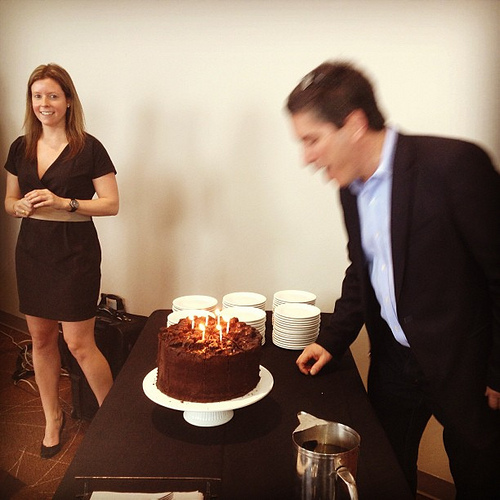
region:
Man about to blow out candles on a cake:
[280, 55, 498, 497]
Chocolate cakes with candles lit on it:
[154, 307, 263, 404]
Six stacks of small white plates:
[166, 289, 321, 353]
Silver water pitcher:
[288, 407, 361, 499]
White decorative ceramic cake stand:
[141, 363, 275, 428]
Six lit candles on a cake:
[185, 308, 234, 342]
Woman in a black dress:
[2, 60, 122, 460]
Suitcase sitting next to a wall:
[70, 288, 146, 420]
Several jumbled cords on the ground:
[8, 326, 74, 393]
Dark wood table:
[48, 310, 398, 498]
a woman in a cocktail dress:
[5, 62, 122, 459]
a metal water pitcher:
[285, 405, 369, 496]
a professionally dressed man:
[279, 69, 499, 490]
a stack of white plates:
[268, 298, 330, 358]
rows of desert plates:
[170, 283, 325, 355]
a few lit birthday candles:
[184, 306, 235, 345]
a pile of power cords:
[8, 328, 55, 395]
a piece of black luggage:
[54, 290, 149, 435]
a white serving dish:
[138, 357, 278, 429]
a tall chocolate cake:
[151, 313, 267, 400]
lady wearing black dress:
[0, 48, 125, 448]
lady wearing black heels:
[23, 397, 111, 477]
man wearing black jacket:
[272, 72, 499, 498]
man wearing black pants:
[362, 331, 499, 488]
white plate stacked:
[156, 283, 338, 387]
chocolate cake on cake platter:
[125, 285, 285, 447]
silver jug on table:
[272, 392, 397, 498]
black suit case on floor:
[60, 276, 180, 448]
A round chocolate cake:
[152, 312, 267, 404]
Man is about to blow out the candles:
[184, 63, 385, 360]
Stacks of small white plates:
[168, 285, 324, 354]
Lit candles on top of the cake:
[181, 307, 239, 347]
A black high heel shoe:
[36, 401, 72, 464]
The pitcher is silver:
[286, 401, 368, 499]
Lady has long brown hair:
[16, 60, 90, 168]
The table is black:
[51, 300, 415, 499]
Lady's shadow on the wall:
[113, 107, 191, 314]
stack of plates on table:
[280, 289, 312, 304]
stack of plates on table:
[246, 309, 268, 329]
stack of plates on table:
[225, 291, 265, 305]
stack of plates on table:
[170, 287, 215, 309]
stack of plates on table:
[166, 307, 195, 323]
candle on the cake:
[215, 327, 227, 339]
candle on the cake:
[223, 318, 230, 330]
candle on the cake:
[201, 320, 213, 343]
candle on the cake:
[184, 317, 195, 328]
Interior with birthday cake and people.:
[5, 4, 497, 494]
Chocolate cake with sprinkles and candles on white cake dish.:
[143, 320, 265, 431]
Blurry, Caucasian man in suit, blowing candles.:
[270, 67, 484, 482]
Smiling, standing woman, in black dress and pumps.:
[0, 53, 115, 455]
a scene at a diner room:
[14, 31, 494, 416]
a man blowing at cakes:
[130, 51, 494, 498]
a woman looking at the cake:
[0, 50, 162, 461]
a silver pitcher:
[280, 398, 370, 498]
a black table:
[44, 301, 431, 498]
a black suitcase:
[57, 282, 169, 439]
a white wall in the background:
[69, 15, 493, 307]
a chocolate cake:
[133, 302, 285, 445]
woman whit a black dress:
[14, 66, 121, 371]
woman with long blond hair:
[1, 75, 93, 300]